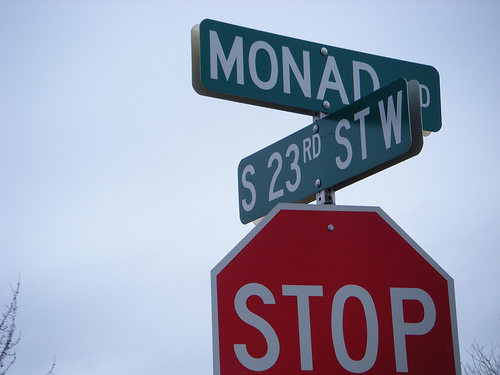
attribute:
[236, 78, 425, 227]
sign — green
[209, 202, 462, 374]
stop sign — red, octagonal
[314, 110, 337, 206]
pole — silver, metal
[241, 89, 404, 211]
letters — white, s 23rd st w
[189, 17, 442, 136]
sign — green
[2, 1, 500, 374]
sky — blue, cloudy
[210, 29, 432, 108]
text — white, monad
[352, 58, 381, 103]
letter — partial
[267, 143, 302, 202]
number — 23